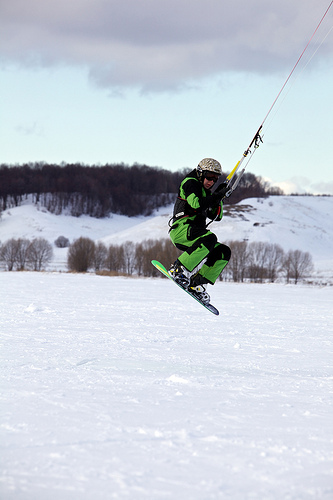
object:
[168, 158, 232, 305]
girl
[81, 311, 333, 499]
snow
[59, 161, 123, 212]
trees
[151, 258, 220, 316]
board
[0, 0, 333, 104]
sky